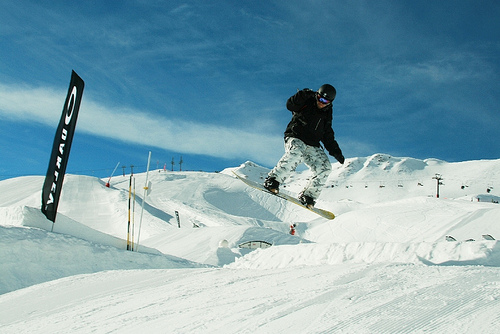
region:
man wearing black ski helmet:
[259, 65, 351, 230]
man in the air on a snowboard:
[228, 64, 365, 227]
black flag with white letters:
[27, 50, 90, 232]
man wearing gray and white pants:
[247, 47, 361, 237]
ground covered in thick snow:
[15, 145, 490, 319]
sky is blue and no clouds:
[6, 5, 481, 158]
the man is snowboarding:
[229, 55, 364, 243]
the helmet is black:
[311, 70, 336, 119]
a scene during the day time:
[6, 8, 498, 331]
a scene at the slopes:
[2, 16, 463, 330]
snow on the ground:
[12, 153, 497, 331]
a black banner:
[20, 55, 129, 270]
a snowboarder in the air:
[215, 55, 422, 220]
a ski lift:
[240, 160, 492, 217]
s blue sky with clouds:
[10, 5, 486, 155]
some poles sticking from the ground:
[106, 125, 163, 290]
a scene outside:
[7, 2, 490, 331]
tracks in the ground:
[68, 255, 386, 332]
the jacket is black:
[283, 85, 345, 156]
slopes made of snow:
[97, 128, 340, 272]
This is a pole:
[433, 175, 445, 202]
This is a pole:
[176, 151, 185, 176]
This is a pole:
[169, 150, 176, 172]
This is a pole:
[160, 158, 169, 175]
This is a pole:
[170, 204, 187, 233]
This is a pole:
[136, 143, 163, 253]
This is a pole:
[124, 162, 142, 249]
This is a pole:
[130, 160, 137, 174]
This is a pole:
[117, 158, 127, 180]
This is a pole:
[95, 158, 121, 187]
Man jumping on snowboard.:
[227, 75, 342, 217]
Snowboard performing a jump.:
[225, 66, 345, 221]